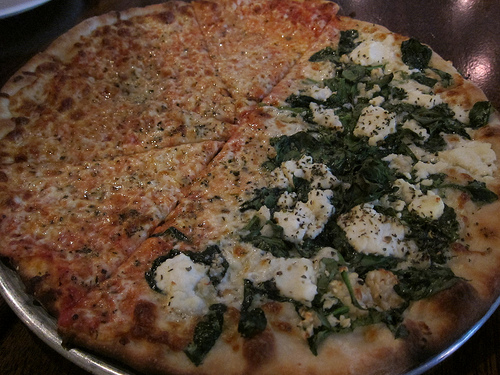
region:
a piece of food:
[31, 31, 265, 139]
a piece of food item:
[9, 151, 208, 286]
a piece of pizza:
[6, 47, 198, 295]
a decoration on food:
[149, 236, 294, 348]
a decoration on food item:
[252, 113, 439, 332]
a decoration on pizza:
[156, 118, 453, 361]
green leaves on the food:
[310, 138, 392, 200]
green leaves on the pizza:
[276, 120, 396, 217]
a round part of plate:
[28, 323, 114, 373]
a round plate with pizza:
[28, 8, 452, 361]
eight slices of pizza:
[3, 2, 498, 374]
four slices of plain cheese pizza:
[1, 0, 339, 341]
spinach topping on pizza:
[176, 58, 467, 339]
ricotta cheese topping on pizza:
[158, 56, 492, 326]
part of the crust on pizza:
[92, 293, 497, 373]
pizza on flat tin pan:
[2, 3, 499, 373]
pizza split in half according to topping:
[2, 1, 499, 366]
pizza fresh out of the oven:
[1, 0, 497, 370]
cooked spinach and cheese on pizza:
[152, 25, 497, 363]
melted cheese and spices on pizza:
[1, 0, 498, 373]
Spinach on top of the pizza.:
[260, 103, 408, 273]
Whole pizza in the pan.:
[61, 24, 488, 339]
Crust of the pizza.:
[335, 318, 470, 366]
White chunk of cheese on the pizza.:
[333, 192, 429, 268]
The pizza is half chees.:
[51, 35, 254, 185]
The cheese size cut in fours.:
[36, 6, 242, 220]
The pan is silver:
[15, 289, 87, 367]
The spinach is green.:
[285, 124, 377, 195]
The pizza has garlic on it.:
[73, 46, 244, 171]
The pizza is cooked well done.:
[63, 55, 432, 341]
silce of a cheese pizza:
[0, 131, 228, 308]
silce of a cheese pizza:
[5, 50, 238, 158]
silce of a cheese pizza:
[35, 2, 247, 121]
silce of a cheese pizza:
[182, 2, 345, 117]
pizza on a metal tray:
[1, 0, 498, 374]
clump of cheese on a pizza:
[149, 252, 206, 317]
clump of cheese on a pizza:
[271, 248, 326, 308]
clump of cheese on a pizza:
[404, 187, 447, 221]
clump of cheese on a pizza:
[353, 102, 399, 147]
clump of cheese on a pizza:
[275, 184, 335, 243]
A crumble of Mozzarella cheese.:
[152, 257, 201, 292]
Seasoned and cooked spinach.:
[344, 128, 371, 193]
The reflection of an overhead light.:
[468, 49, 497, 86]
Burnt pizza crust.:
[452, 293, 474, 327]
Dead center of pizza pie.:
[203, 91, 304, 181]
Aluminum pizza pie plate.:
[2, 268, 56, 373]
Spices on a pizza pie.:
[84, 199, 162, 250]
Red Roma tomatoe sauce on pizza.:
[292, 4, 337, 46]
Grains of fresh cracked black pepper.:
[467, 215, 498, 263]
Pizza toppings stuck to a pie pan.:
[54, 331, 81, 358]